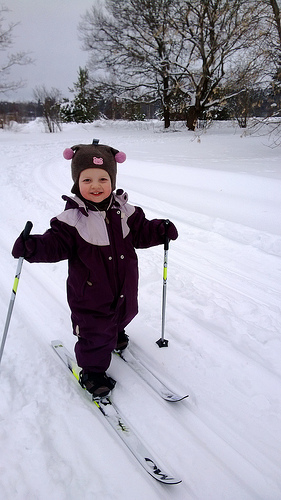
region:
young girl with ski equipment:
[5, 137, 190, 483]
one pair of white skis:
[3, 365, 192, 487]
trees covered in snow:
[41, 2, 277, 129]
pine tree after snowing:
[52, 67, 101, 125]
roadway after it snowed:
[207, 208, 275, 493]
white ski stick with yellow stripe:
[154, 242, 178, 351]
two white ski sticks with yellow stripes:
[3, 254, 172, 345]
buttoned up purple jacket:
[35, 195, 142, 341]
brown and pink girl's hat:
[57, 140, 133, 174]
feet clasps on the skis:
[69, 329, 137, 395]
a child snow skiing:
[58, 139, 180, 471]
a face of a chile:
[80, 172, 110, 199]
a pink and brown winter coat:
[57, 193, 139, 322]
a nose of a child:
[90, 177, 99, 191]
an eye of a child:
[80, 175, 89, 183]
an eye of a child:
[97, 175, 108, 184]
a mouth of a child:
[86, 189, 104, 196]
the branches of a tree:
[206, 39, 244, 66]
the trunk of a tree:
[158, 87, 173, 128]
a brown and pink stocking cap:
[56, 133, 136, 173]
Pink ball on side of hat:
[111, 148, 127, 164]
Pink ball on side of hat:
[59, 143, 78, 163]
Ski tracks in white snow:
[191, 421, 253, 483]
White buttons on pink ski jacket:
[103, 253, 129, 264]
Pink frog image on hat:
[87, 153, 105, 166]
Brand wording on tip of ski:
[140, 451, 180, 484]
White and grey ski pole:
[148, 225, 179, 356]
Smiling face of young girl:
[71, 163, 116, 207]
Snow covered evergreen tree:
[56, 63, 106, 123]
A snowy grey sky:
[11, 13, 75, 78]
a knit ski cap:
[62, 138, 125, 192]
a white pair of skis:
[51, 337, 181, 486]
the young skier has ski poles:
[156, 217, 169, 348]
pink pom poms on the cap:
[115, 151, 127, 162]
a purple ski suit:
[22, 194, 176, 372]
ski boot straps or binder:
[79, 369, 114, 401]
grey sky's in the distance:
[0, 1, 279, 96]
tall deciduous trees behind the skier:
[99, 0, 280, 132]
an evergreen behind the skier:
[61, 66, 103, 124]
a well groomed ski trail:
[180, 167, 280, 499]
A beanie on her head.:
[59, 141, 127, 193]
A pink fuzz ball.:
[57, 145, 77, 160]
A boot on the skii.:
[75, 368, 115, 399]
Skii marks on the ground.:
[190, 421, 260, 498]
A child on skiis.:
[11, 140, 192, 486]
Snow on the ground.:
[146, 137, 210, 177]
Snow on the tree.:
[159, 53, 244, 133]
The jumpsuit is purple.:
[30, 187, 163, 372]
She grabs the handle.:
[157, 218, 180, 247]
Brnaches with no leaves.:
[1, 0, 33, 94]